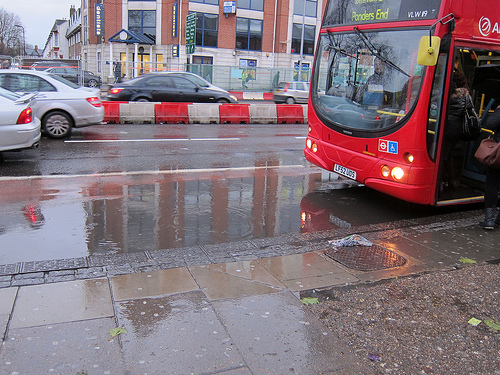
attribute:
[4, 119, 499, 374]
cement — wet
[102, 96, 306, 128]
barricade — Red , white 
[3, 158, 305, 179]
line — dividing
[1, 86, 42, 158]
car — silver 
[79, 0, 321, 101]
building — multi story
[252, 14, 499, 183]
bus — city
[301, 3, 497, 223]
bus — red 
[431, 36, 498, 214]
door — loading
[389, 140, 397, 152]
handicap sticker — Blue 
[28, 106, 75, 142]
wheel — rear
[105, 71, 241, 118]
car — black , compact 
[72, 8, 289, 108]
building — red, brick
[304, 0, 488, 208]
bus — red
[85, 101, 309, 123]
barrier — Red , white 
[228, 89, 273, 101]
barrier — Red , white 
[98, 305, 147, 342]
leaf — Green 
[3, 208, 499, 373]
sidewalk — concrete 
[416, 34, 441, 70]
mirror — side, view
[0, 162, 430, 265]
cement — wet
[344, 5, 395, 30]
sign — LED, route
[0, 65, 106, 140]
car — silver 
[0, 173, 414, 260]
puddle — giant